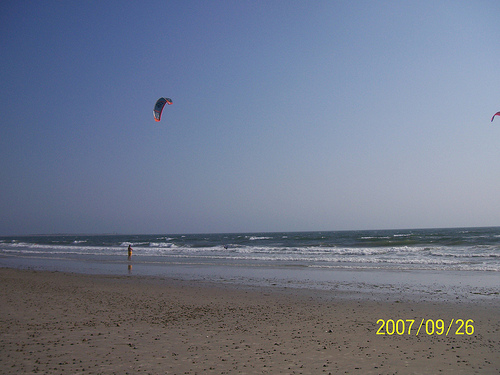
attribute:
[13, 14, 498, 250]
sky — blue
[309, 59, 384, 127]
clouds — white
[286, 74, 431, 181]
sky — blue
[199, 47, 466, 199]
sky — blue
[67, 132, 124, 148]
clouds — white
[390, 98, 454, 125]
clouds — white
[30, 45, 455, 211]
sky — blue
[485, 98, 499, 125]
parachute — colored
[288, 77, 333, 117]
ground — churning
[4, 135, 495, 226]
clouds — white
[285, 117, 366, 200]
clouds — white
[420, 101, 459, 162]
clouds — white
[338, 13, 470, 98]
sky — blue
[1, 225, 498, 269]
ocean — deep, blue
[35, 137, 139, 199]
cloud — white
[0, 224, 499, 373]
beach — sandy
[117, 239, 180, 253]
wave — large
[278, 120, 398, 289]
clouds — white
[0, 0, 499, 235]
clouds — white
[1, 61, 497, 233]
cloud — white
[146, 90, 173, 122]
parachute — red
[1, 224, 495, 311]
ocean water — white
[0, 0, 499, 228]
sky — blue, clear, light blue, hazy blue, hazy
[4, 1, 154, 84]
clouds — white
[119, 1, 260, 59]
clouds — white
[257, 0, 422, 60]
clouds — white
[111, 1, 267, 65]
clouds — white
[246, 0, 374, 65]
clouds — white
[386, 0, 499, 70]
clouds — white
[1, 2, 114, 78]
clouds — white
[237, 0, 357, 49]
clouds — white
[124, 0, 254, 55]
clouds — white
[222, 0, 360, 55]
clouds — white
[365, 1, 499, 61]
clouds — white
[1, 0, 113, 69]
clouds — white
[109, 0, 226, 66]
clouds — white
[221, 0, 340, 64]
clouds — white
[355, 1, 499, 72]
clouds — white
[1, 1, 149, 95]
clouds — white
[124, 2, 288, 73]
clouds — white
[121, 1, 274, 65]
clouds — white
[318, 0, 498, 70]
clouds — white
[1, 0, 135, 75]
clouds — white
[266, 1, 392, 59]
clouds — white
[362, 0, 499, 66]
clouds — white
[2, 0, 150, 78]
clouds — white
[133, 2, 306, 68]
clouds — white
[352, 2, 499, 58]
clouds — white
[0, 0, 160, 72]
clouds — white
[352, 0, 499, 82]
clouds — white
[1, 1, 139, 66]
clouds — white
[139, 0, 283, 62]
clouds — white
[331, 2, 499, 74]
clouds — white